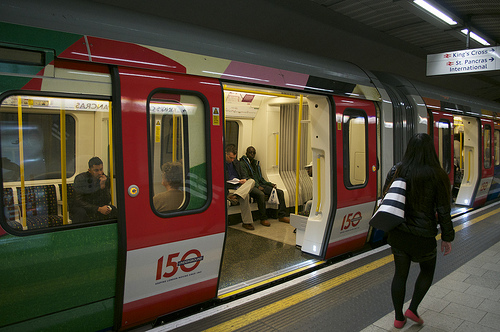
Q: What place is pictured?
A: It is a station.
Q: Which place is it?
A: It is a station.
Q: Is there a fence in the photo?
A: No, there are no fences.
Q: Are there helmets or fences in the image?
A: No, there are no fences or helmets.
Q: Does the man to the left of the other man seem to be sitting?
A: Yes, the man is sitting.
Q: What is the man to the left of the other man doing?
A: The man is sitting.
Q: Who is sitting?
A: The man is sitting.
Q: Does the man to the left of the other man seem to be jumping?
A: No, the man is sitting.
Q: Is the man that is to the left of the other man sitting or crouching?
A: The man is sitting.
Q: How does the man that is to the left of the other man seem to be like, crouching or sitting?
A: The man is sitting.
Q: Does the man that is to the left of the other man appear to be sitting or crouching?
A: The man is sitting.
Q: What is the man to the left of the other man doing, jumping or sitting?
A: The man is sitting.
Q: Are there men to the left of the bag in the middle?
A: Yes, there is a man to the left of the bag.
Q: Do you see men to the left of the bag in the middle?
A: Yes, there is a man to the left of the bag.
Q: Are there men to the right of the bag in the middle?
A: No, the man is to the left of the bag.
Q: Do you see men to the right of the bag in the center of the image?
A: No, the man is to the left of the bag.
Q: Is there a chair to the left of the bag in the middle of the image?
A: No, there is a man to the left of the bag.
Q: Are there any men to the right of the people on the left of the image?
A: Yes, there is a man to the right of the people.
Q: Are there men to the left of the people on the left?
A: No, the man is to the right of the people.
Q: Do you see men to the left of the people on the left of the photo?
A: No, the man is to the right of the people.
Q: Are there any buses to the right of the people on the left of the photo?
A: No, there is a man to the right of the people.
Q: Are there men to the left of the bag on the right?
A: Yes, there is a man to the left of the bag.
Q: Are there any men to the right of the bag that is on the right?
A: No, the man is to the left of the bag.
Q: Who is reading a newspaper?
A: The man is reading a newspaper.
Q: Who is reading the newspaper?
A: The man is reading a newspaper.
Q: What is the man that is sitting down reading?
A: The man is reading a newspaper.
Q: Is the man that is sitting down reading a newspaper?
A: Yes, the man is reading a newspaper.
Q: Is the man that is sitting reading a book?
A: No, the man is reading a newspaper.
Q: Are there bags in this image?
A: Yes, there is a bag.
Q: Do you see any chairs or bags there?
A: Yes, there is a bag.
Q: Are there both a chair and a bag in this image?
A: No, there is a bag but no chairs.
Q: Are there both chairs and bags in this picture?
A: No, there is a bag but no chairs.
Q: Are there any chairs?
A: No, there are no chairs.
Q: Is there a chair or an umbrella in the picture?
A: No, there are no chairs or umbrellas.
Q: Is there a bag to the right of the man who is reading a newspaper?
A: Yes, there is a bag to the right of the man.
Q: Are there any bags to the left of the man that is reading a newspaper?
A: No, the bag is to the right of the man.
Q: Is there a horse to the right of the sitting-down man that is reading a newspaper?
A: No, there is a bag to the right of the man.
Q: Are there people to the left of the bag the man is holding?
A: Yes, there are people to the left of the bag.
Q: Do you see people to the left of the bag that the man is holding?
A: Yes, there are people to the left of the bag.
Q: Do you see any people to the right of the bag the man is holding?
A: No, the people are to the left of the bag.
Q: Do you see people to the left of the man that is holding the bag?
A: Yes, there are people to the left of the man.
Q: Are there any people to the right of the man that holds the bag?
A: No, the people are to the left of the man.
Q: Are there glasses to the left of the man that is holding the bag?
A: No, there are people to the left of the man.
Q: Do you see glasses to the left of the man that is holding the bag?
A: No, there are people to the left of the man.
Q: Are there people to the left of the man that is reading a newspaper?
A: Yes, there are people to the left of the man.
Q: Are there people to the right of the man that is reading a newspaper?
A: No, the people are to the left of the man.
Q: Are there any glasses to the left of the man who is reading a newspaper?
A: No, there are people to the left of the man.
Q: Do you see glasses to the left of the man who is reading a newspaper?
A: No, there are people to the left of the man.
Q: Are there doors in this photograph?
A: Yes, there are doors.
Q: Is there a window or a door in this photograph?
A: Yes, there are doors.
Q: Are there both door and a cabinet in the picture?
A: No, there are doors but no cabinets.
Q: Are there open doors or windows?
A: Yes, there are open doors.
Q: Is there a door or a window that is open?
A: Yes, the doors are open.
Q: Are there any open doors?
A: Yes, there are open doors.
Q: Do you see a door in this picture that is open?
A: Yes, there are doors that are open.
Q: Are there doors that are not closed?
A: Yes, there are open doors.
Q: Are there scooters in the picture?
A: No, there are no scooters.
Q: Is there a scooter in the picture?
A: No, there are no scooters.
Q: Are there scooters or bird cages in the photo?
A: No, there are no scooters or bird cages.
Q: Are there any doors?
A: Yes, there is a door.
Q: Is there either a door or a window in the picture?
A: Yes, there is a door.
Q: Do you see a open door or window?
A: Yes, there is an open door.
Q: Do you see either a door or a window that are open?
A: Yes, the door is open.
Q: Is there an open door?
A: Yes, there is an open door.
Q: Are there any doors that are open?
A: Yes, there is a door that is open.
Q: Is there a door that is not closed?
A: Yes, there is a open door.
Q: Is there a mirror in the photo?
A: No, there are no mirrors.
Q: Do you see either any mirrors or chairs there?
A: No, there are no mirrors or chairs.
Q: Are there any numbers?
A: Yes, there are numbers.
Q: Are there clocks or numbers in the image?
A: Yes, there are numbers.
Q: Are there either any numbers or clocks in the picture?
A: Yes, there are numbers.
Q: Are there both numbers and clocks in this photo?
A: No, there are numbers but no clocks.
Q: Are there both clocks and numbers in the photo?
A: No, there are numbers but no clocks.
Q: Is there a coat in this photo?
A: Yes, there is a coat.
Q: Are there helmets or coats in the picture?
A: Yes, there is a coat.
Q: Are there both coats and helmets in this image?
A: No, there is a coat but no helmets.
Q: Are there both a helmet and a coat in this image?
A: No, there is a coat but no helmets.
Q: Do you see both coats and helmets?
A: No, there is a coat but no helmets.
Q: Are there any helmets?
A: No, there are no helmets.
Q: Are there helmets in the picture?
A: No, there are no helmets.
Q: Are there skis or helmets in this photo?
A: No, there are no helmets or skis.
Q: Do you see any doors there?
A: Yes, there is a door.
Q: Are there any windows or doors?
A: Yes, there is a door.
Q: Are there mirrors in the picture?
A: No, there are no mirrors.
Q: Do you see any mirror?
A: No, there are no mirrors.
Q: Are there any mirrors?
A: No, there are no mirrors.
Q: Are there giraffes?
A: Yes, there is a giraffe.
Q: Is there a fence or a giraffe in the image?
A: Yes, there is a giraffe.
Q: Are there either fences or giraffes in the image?
A: Yes, there is a giraffe.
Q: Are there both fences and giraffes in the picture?
A: No, there is a giraffe but no fences.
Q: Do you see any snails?
A: No, there are no snails.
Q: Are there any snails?
A: No, there are no snails.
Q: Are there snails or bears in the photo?
A: No, there are no snails or bears.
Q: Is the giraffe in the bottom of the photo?
A: Yes, the giraffe is in the bottom of the image.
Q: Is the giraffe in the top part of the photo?
A: No, the giraffe is in the bottom of the image.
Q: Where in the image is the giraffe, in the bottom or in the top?
A: The giraffe is in the bottom of the image.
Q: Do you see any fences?
A: No, there are no fences.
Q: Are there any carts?
A: No, there are no carts.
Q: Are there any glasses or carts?
A: No, there are no carts or glasses.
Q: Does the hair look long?
A: Yes, the hair is long.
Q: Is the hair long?
A: Yes, the hair is long.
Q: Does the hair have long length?
A: Yes, the hair is long.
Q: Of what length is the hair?
A: The hair is long.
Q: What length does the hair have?
A: The hair has long length.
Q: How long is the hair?
A: The hair is long.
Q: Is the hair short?
A: No, the hair is long.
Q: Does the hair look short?
A: No, the hair is long.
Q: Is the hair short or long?
A: The hair is long.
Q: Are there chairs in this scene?
A: No, there are no chairs.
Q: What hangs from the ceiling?
A: The sign hangs from the ceiling.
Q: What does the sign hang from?
A: The sign hangs from the ceiling.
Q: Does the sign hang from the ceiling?
A: Yes, the sign hangs from the ceiling.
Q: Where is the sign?
A: The sign is in the station.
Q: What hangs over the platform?
A: The sign hangs over the platform.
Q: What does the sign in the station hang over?
A: The sign hangs over the platform.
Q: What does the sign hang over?
A: The sign hangs over the platform.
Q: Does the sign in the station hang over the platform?
A: Yes, the sign hangs over the platform.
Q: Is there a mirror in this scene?
A: No, there are no mirrors.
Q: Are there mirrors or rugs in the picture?
A: No, there are no mirrors or rugs.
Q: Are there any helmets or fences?
A: No, there are no helmets or fences.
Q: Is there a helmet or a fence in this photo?
A: No, there are no helmets or fences.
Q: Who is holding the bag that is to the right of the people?
A: The man is holding the bag.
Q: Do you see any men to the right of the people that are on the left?
A: Yes, there is a man to the right of the people.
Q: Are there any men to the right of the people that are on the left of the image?
A: Yes, there is a man to the right of the people.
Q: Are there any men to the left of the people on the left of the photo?
A: No, the man is to the right of the people.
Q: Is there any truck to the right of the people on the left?
A: No, there is a man to the right of the people.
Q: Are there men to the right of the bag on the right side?
A: No, the man is to the left of the bag.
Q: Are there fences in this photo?
A: No, there are no fences.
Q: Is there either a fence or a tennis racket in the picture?
A: No, there are no fences or rackets.